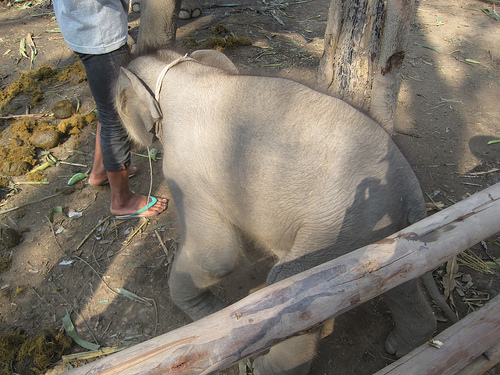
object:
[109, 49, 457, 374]
elephant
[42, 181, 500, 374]
fence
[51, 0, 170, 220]
person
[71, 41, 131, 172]
jeans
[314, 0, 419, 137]
trunk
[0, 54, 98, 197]
poop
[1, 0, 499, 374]
ground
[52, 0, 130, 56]
shirt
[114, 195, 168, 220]
flip flop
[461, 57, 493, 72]
leaf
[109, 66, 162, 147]
ears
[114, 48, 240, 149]
head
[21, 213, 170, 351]
shadow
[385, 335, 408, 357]
toe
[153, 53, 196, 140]
string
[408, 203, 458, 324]
tail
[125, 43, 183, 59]
hair